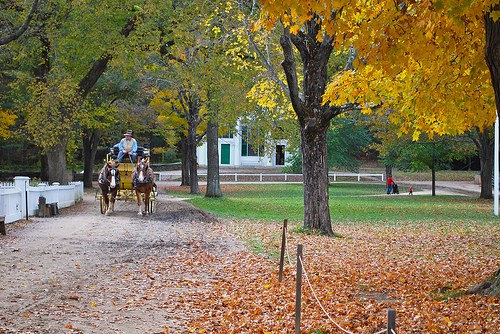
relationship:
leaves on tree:
[366, 33, 465, 113] [248, 44, 383, 256]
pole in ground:
[292, 237, 308, 324] [6, 173, 498, 331]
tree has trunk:
[245, 1, 474, 235] [282, 26, 346, 239]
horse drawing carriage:
[96, 160, 123, 217] [94, 139, 159, 215]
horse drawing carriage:
[129, 156, 156, 217] [94, 139, 159, 215]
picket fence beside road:
[1, 175, 85, 226] [0, 180, 265, 332]